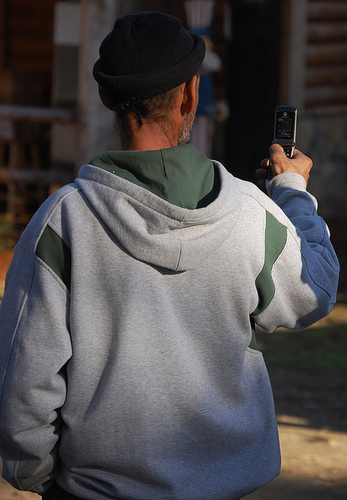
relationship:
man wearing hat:
[6, 5, 328, 498] [91, 11, 204, 102]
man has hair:
[6, 5, 328, 498] [101, 69, 180, 136]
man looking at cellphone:
[6, 5, 328, 498] [269, 104, 296, 181]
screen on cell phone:
[274, 116, 293, 142] [265, 104, 298, 177]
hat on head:
[91, 11, 204, 102] [89, 9, 205, 142]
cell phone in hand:
[264, 101, 300, 181] [254, 138, 318, 199]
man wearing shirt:
[6, 5, 328, 498] [4, 149, 335, 498]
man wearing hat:
[6, 5, 328, 498] [91, 4, 206, 109]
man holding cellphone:
[6, 5, 328, 498] [265, 106, 305, 167]